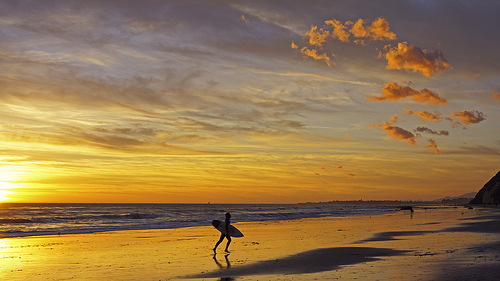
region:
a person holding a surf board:
[214, 186, 244, 279]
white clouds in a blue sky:
[285, 16, 464, 74]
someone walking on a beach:
[393, 205, 430, 230]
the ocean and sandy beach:
[49, 196, 204, 267]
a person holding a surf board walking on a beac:
[181, 204, 248, 275]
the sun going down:
[0, 143, 20, 243]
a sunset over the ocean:
[1, 92, 36, 279]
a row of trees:
[297, 191, 426, 211]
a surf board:
[205, 220, 242, 235]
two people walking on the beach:
[193, 169, 441, 265]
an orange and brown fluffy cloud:
[365, 78, 447, 108]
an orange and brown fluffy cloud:
[379, 121, 414, 144]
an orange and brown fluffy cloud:
[425, 136, 439, 157]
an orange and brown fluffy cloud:
[446, 104, 487, 130]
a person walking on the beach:
[208, 209, 240, 254]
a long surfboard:
[210, 216, 243, 241]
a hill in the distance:
[468, 162, 498, 212]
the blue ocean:
[0, 198, 470, 236]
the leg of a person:
[207, 233, 223, 255]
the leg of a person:
[224, 236, 236, 250]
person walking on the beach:
[199, 202, 243, 266]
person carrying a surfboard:
[197, 198, 257, 264]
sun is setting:
[0, 158, 30, 203]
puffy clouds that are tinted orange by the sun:
[371, 114, 423, 144]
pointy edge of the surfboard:
[239, 227, 249, 242]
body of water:
[3, 198, 438, 233]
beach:
[1, 200, 499, 279]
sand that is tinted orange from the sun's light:
[2, 236, 97, 276]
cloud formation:
[359, 38, 484, 161]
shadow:
[209, 255, 250, 280]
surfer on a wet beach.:
[197, 196, 267, 278]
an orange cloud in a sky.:
[377, 29, 452, 88]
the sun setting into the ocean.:
[0, 146, 52, 210]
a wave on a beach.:
[331, 225, 499, 250]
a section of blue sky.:
[114, 34, 130, 39]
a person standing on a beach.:
[401, 206, 418, 225]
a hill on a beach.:
[443, 170, 499, 207]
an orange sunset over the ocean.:
[0, 145, 498, 203]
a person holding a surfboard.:
[206, 215, 249, 244]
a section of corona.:
[15, 166, 36, 195]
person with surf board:
[206, 197, 248, 262]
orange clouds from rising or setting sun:
[279, 9, 496, 162]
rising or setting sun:
[0, 139, 57, 204]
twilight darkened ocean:
[4, 205, 446, 237]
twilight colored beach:
[0, 218, 211, 277]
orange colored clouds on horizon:
[54, 158, 496, 198]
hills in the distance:
[454, 161, 499, 206]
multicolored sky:
[1, 7, 498, 189]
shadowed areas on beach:
[203, 242, 498, 278]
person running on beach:
[201, 193, 250, 261]